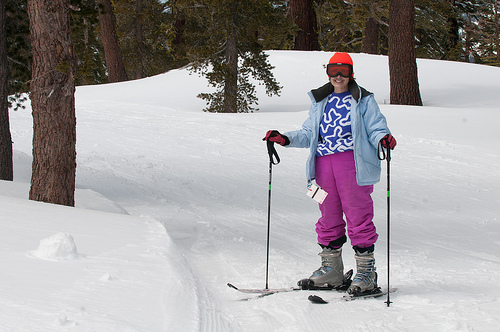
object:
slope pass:
[73, 101, 489, 262]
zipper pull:
[311, 187, 320, 199]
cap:
[328, 52, 354, 78]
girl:
[263, 46, 398, 295]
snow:
[0, 43, 500, 332]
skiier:
[264, 48, 397, 296]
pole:
[384, 145, 393, 307]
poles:
[263, 134, 275, 293]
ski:
[225, 269, 356, 294]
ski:
[307, 287, 399, 304]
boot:
[297, 243, 345, 289]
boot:
[347, 244, 379, 293]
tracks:
[408, 140, 479, 187]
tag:
[306, 184, 328, 205]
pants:
[313, 148, 380, 252]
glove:
[265, 129, 291, 146]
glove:
[380, 134, 397, 150]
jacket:
[279, 80, 389, 187]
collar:
[310, 80, 361, 102]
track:
[200, 223, 290, 332]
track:
[287, 248, 358, 332]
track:
[94, 154, 210, 196]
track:
[212, 125, 312, 147]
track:
[235, 212, 315, 242]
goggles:
[326, 63, 351, 77]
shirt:
[315, 92, 357, 158]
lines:
[319, 95, 344, 148]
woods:
[64, 15, 266, 115]